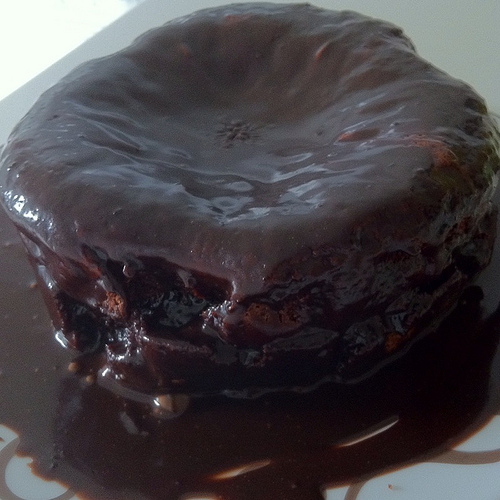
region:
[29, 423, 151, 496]
Chocolate on the plate.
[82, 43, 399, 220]
A dip in the cake.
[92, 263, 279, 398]
The cake is chocolate.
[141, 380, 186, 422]
Bubble in the chocolate.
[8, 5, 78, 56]
White in the background.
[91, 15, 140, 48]
A shadow is being cast.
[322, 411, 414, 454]
White in the chocolate.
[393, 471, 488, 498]
The plate is white.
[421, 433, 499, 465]
Brown line on the plate.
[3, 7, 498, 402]
Dessert is shaped like a cupcake.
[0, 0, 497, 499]
chocolate dessert cake with sauce on white plate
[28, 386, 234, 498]
chocolate sauce on white plate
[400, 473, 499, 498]
corner of white plate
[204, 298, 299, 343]
chocolate cake pastry crumb on side of cake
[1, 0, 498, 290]
top of chocolate cake and icing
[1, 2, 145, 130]
edge of white table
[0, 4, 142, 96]
white background and edge of white table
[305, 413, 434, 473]
white plate with chocolate sauce on it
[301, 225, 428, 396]
side of chocolate cake and layers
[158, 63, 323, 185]
dip in center of chocolate cake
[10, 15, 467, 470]
a chocolate desert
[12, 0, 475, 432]
a small chocolate cake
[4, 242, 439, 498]
chocolate syrup surrounding the desert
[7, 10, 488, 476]
a baked chocolate desert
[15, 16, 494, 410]
a thick chocolate desert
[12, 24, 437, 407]
a small bake chocolate desert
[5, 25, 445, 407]
a desert with chocolate frosting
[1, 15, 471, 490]
a desert with chocolate frosting and syrup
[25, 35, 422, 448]
a desert with chocolate glaze and syrup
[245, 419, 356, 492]
plate the is clear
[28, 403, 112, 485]
plate that is reflective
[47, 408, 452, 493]
reflections on clear plate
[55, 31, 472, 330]
chocolate dessert on a plate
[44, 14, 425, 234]
a dip in the middle of the food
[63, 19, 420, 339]
chocolate frosting covering dessert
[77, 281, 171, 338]
light brown part of dessert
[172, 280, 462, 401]
dark brown edge of dessert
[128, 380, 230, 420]
sauce of dessert that spilled to plate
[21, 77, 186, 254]
sauce of dessert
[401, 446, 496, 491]
White plate with a brown decorative line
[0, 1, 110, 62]
Light source in the left corner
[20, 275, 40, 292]
Bubble in chocolate sauce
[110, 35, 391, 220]
Dip on the top of a chocolate cake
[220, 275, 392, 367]
Layers of chocolate cake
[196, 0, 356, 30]
Top of a chocolate cake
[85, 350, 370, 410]
Bottom of a chocolate cake on chocolate sauce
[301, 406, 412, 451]
White plate in the hole of chocolate sauce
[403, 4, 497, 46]
Shadowed corner of a white plate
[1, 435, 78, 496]
Brown circle on a white plate